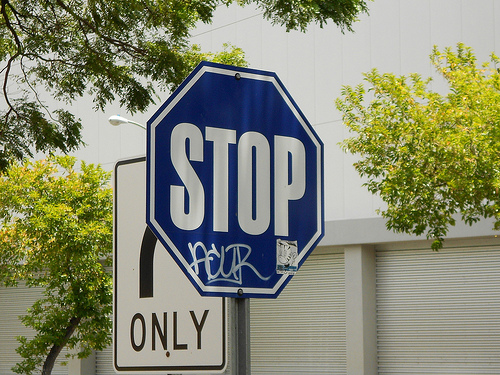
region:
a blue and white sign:
[145, 61, 322, 292]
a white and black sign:
[107, 152, 227, 367]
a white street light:
[107, 110, 144, 127]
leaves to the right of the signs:
[335, 40, 495, 250]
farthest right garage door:
[372, 245, 494, 372]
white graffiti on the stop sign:
[187, 240, 267, 280]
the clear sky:
[1, 0, 496, 215]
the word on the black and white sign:
[130, 307, 207, 352]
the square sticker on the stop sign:
[275, 235, 300, 270]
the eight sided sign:
[143, 63, 327, 298]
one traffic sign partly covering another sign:
[113, 52, 328, 362]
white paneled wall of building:
[5, 5, 486, 230]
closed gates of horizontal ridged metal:
[5, 230, 490, 365]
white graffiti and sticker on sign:
[150, 60, 325, 295]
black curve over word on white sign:
[110, 150, 225, 370]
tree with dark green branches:
[5, 0, 367, 180]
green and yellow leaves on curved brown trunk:
[0, 155, 117, 366]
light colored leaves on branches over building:
[335, 35, 495, 251]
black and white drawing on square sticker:
[275, 237, 300, 273]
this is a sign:
[135, 53, 342, 313]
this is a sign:
[94, 148, 241, 374]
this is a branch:
[329, 75, 494, 213]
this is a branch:
[24, 158, 84, 273]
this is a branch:
[14, 37, 94, 165]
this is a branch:
[28, 49, 116, 119]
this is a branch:
[54, 0, 192, 99]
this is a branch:
[95, 8, 156, 40]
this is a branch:
[7, 227, 69, 320]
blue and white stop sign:
[142, 58, 329, 303]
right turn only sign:
[111, 150, 230, 374]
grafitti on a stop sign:
[181, 232, 270, 290]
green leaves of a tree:
[328, 39, 498, 254]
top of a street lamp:
[103, 113, 148, 135]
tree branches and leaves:
[2, 1, 371, 176]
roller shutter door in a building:
[235, 243, 353, 371]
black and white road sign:
[110, 157, 230, 374]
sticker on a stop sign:
[270, 234, 302, 280]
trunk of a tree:
[30, 285, 88, 373]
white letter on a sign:
[270, 130, 308, 237]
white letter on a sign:
[233, 128, 275, 238]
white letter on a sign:
[206, 124, 238, 236]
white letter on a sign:
[161, 118, 211, 237]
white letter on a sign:
[185, 239, 212, 282]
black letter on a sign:
[187, 303, 207, 354]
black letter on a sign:
[170, 307, 188, 352]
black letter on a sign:
[146, 307, 171, 352]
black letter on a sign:
[126, 310, 146, 356]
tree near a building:
[322, 33, 499, 268]